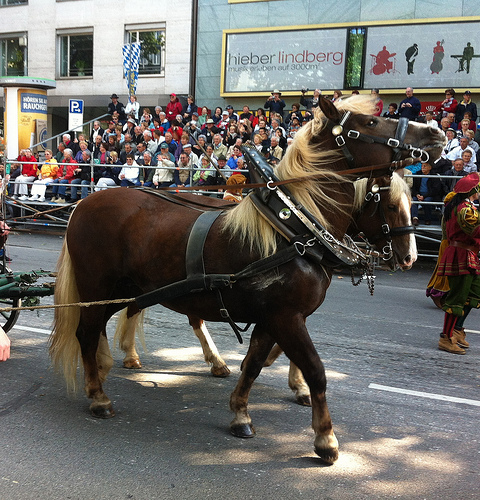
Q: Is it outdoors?
A: Yes, it is outdoors.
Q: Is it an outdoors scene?
A: Yes, it is outdoors.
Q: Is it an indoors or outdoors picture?
A: It is outdoors.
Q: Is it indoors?
A: No, it is outdoors.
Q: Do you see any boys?
A: No, there are no boys.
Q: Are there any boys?
A: No, there are no boys.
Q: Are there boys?
A: No, there are no boys.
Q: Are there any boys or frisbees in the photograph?
A: No, there are no boys or frisbees.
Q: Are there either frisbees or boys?
A: No, there are no boys or frisbees.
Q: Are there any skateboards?
A: No, there are no skateboards.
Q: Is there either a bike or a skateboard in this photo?
A: No, there are no skateboards or bikes.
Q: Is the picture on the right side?
A: Yes, the picture is on the right of the image.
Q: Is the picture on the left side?
A: No, the picture is on the right of the image.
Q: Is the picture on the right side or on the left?
A: The picture is on the right of the image.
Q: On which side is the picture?
A: The picture is on the right of the image.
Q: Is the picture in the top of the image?
A: Yes, the picture is in the top of the image.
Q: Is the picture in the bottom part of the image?
A: No, the picture is in the top of the image.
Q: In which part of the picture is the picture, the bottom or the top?
A: The picture is in the top of the image.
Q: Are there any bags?
A: No, there are no bags.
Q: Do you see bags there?
A: No, there are no bags.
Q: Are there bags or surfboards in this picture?
A: No, there are no bags or surfboards.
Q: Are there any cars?
A: No, there are no cars.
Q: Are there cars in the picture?
A: No, there are no cars.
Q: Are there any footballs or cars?
A: No, there are no cars or footballs.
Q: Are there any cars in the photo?
A: No, there are no cars.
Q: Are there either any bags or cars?
A: No, there are no cars or bags.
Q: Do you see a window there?
A: Yes, there is a window.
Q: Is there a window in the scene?
A: Yes, there is a window.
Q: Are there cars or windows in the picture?
A: Yes, there is a window.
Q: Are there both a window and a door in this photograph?
A: No, there is a window but no doors.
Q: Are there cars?
A: No, there are no cars.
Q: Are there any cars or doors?
A: No, there are no cars or doors.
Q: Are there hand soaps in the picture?
A: No, there are no hand soaps.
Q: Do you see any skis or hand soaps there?
A: No, there are no hand soaps or skis.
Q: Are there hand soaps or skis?
A: No, there are no hand soaps or skis.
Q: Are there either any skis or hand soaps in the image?
A: No, there are no hand soaps or skis.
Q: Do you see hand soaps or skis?
A: No, there are no hand soaps or skis.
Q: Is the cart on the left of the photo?
A: Yes, the cart is on the left of the image.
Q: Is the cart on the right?
A: No, the cart is on the left of the image.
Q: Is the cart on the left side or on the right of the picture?
A: The cart is on the left of the image.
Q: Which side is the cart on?
A: The cart is on the left of the image.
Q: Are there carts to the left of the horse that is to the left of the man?
A: Yes, there is a cart to the left of the horse.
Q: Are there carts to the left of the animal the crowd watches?
A: Yes, there is a cart to the left of the horse.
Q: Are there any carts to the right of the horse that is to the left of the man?
A: No, the cart is to the left of the horse.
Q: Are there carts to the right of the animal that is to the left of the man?
A: No, the cart is to the left of the horse.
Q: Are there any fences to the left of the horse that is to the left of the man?
A: No, there is a cart to the left of the horse.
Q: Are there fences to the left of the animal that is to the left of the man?
A: No, there is a cart to the left of the horse.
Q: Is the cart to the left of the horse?
A: Yes, the cart is to the left of the horse.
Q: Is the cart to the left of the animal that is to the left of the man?
A: Yes, the cart is to the left of the horse.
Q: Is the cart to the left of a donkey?
A: No, the cart is to the left of the horse.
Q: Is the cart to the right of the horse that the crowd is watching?
A: No, the cart is to the left of the horse.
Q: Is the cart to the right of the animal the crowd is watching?
A: No, the cart is to the left of the horse.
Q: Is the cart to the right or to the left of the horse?
A: The cart is to the left of the horse.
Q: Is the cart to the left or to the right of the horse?
A: The cart is to the left of the horse.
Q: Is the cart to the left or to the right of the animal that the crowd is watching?
A: The cart is to the left of the horse.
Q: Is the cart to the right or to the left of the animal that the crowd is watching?
A: The cart is to the left of the horse.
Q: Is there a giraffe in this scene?
A: No, there are no giraffes.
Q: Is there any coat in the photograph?
A: Yes, there is a coat.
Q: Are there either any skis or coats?
A: Yes, there is a coat.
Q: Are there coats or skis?
A: Yes, there is a coat.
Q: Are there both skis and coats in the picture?
A: No, there is a coat but no skis.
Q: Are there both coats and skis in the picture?
A: No, there is a coat but no skis.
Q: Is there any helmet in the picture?
A: No, there are no helmets.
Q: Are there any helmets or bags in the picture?
A: No, there are no helmets or bags.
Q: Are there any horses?
A: Yes, there is a horse.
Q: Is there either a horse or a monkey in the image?
A: Yes, there is a horse.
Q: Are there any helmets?
A: No, there are no helmets.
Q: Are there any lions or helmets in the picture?
A: No, there are no helmets or lions.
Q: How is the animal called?
A: The animal is a horse.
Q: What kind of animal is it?
A: The animal is a horse.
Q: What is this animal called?
A: This is a horse.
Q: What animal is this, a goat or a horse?
A: This is a horse.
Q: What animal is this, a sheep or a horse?
A: This is a horse.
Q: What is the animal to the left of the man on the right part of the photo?
A: The animal is a horse.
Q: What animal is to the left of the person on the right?
A: The animal is a horse.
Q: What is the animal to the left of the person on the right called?
A: The animal is a horse.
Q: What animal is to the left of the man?
A: The animal is a horse.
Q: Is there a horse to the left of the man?
A: Yes, there is a horse to the left of the man.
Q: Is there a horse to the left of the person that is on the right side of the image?
A: Yes, there is a horse to the left of the man.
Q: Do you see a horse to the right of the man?
A: No, the horse is to the left of the man.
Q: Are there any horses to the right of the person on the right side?
A: No, the horse is to the left of the man.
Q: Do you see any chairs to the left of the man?
A: No, there is a horse to the left of the man.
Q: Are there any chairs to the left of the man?
A: No, there is a horse to the left of the man.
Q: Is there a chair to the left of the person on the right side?
A: No, there is a horse to the left of the man.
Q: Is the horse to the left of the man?
A: Yes, the horse is to the left of the man.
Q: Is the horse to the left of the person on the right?
A: Yes, the horse is to the left of the man.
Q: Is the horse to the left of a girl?
A: No, the horse is to the left of the man.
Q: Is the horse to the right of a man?
A: No, the horse is to the left of a man.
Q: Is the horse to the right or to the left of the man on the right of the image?
A: The horse is to the left of the man.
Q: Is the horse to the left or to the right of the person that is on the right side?
A: The horse is to the left of the man.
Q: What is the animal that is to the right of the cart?
A: The animal is a horse.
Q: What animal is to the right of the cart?
A: The animal is a horse.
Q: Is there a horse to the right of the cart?
A: Yes, there is a horse to the right of the cart.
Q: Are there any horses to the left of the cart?
A: No, the horse is to the right of the cart.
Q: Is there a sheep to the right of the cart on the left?
A: No, there is a horse to the right of the cart.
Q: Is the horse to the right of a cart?
A: Yes, the horse is to the right of a cart.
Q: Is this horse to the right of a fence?
A: No, the horse is to the right of a cart.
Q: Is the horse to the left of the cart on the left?
A: No, the horse is to the right of the cart.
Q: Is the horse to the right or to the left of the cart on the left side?
A: The horse is to the right of the cart.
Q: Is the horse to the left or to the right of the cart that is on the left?
A: The horse is to the right of the cart.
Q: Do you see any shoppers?
A: No, there are no shoppers.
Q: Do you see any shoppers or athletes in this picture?
A: No, there are no shoppers or athletes.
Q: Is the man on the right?
A: Yes, the man is on the right of the image.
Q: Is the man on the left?
A: No, the man is on the right of the image.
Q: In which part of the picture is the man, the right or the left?
A: The man is on the right of the image.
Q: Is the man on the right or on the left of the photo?
A: The man is on the right of the image.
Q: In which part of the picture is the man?
A: The man is on the right of the image.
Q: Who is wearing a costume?
A: The man is wearing a costume.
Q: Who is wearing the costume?
A: The man is wearing a costume.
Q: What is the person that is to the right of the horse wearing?
A: The man is wearing a costume.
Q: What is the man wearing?
A: The man is wearing a costume.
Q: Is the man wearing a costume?
A: Yes, the man is wearing a costume.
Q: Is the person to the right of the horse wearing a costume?
A: Yes, the man is wearing a costume.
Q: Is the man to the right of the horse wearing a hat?
A: No, the man is wearing a costume.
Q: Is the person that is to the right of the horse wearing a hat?
A: No, the man is wearing a costume.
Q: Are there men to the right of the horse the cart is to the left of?
A: Yes, there is a man to the right of the horse.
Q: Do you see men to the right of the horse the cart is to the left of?
A: Yes, there is a man to the right of the horse.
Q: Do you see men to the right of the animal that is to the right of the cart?
A: Yes, there is a man to the right of the horse.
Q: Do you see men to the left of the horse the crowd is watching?
A: No, the man is to the right of the horse.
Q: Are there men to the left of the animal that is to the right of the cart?
A: No, the man is to the right of the horse.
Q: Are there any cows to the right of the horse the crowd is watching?
A: No, there is a man to the right of the horse.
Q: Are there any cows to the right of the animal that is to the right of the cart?
A: No, there is a man to the right of the horse.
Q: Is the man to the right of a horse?
A: Yes, the man is to the right of a horse.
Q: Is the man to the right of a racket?
A: No, the man is to the right of a horse.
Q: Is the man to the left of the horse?
A: No, the man is to the right of the horse.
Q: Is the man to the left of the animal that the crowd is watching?
A: No, the man is to the right of the horse.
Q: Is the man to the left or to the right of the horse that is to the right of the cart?
A: The man is to the right of the horse.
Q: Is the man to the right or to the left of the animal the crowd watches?
A: The man is to the right of the horse.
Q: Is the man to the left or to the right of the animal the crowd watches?
A: The man is to the right of the horse.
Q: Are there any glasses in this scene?
A: No, there are no glasses.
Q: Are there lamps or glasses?
A: No, there are no glasses or lamps.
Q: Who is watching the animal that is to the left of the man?
A: The crowd is watching the horse.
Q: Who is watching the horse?
A: The crowd is watching the horse.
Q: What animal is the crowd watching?
A: The crowd is watching the horse.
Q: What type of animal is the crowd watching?
A: The crowd is watching the horse.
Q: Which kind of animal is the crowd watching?
A: The crowd is watching the horse.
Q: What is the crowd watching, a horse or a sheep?
A: The crowd is watching a horse.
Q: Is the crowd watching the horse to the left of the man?
A: Yes, the crowd is watching the horse.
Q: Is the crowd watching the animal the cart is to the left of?
A: Yes, the crowd is watching the horse.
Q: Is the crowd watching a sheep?
A: No, the crowd is watching the horse.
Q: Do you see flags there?
A: Yes, there is a flag.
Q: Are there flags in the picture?
A: Yes, there is a flag.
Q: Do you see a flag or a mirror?
A: Yes, there is a flag.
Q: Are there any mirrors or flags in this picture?
A: Yes, there is a flag.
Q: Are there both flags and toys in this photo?
A: No, there is a flag but no toys.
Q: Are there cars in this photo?
A: No, there are no cars.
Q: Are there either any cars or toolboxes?
A: No, there are no cars or toolboxes.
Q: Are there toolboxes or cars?
A: No, there are no cars or toolboxes.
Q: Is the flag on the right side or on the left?
A: The flag is on the left of the image.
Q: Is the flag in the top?
A: Yes, the flag is in the top of the image.